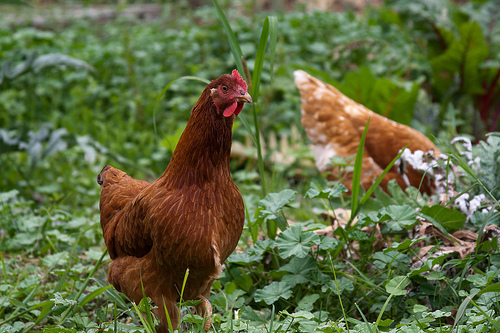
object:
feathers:
[181, 164, 226, 222]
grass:
[1, 8, 484, 331]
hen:
[96, 69, 253, 333]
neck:
[161, 116, 236, 177]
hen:
[292, 68, 452, 200]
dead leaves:
[296, 205, 497, 279]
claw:
[194, 295, 213, 332]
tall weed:
[211, 0, 285, 259]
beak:
[239, 92, 253, 104]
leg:
[104, 259, 179, 329]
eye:
[220, 84, 229, 92]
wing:
[359, 113, 424, 188]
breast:
[137, 181, 245, 300]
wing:
[104, 193, 151, 258]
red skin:
[217, 96, 245, 118]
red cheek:
[216, 82, 241, 100]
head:
[208, 69, 252, 118]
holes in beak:
[238, 90, 244, 95]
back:
[96, 164, 138, 196]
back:
[290, 68, 369, 137]